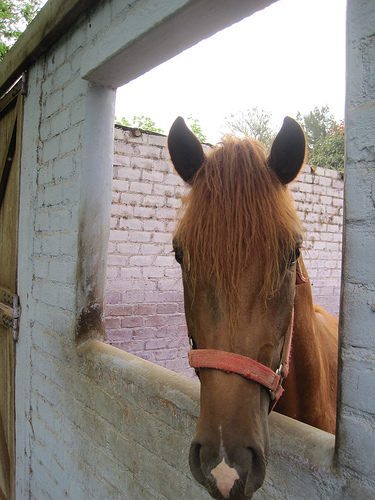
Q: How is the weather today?
A: It is sunny.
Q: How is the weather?
A: It is sunny.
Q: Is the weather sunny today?
A: Yes, it is sunny.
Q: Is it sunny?
A: Yes, it is sunny.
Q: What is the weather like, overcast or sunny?
A: It is sunny.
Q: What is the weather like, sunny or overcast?
A: It is sunny.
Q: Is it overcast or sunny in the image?
A: It is sunny.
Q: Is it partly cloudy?
A: No, it is sunny.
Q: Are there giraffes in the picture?
A: No, there are no giraffes.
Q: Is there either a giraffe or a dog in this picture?
A: No, there are no giraffes or dogs.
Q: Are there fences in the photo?
A: No, there are no fences.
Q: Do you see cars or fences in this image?
A: No, there are no fences or cars.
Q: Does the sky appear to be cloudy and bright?
A: No, the sky is bright but sunny.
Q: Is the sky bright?
A: Yes, the sky is bright.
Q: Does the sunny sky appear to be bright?
A: Yes, the sky is bright.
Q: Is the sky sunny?
A: Yes, the sky is sunny.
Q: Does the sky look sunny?
A: Yes, the sky is sunny.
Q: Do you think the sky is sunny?
A: Yes, the sky is sunny.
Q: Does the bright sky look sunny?
A: Yes, the sky is sunny.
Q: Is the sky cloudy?
A: No, the sky is sunny.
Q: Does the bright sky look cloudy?
A: No, the sky is sunny.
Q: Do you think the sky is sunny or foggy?
A: The sky is sunny.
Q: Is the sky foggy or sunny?
A: The sky is sunny.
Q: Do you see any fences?
A: No, there are no fences.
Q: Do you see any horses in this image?
A: Yes, there is a horse.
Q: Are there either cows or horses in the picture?
A: Yes, there is a horse.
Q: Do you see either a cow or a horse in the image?
A: Yes, there is a horse.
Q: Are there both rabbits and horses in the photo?
A: No, there is a horse but no rabbits.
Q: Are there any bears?
A: No, there are no bears.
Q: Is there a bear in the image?
A: No, there are no bears.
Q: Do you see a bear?
A: No, there are no bears.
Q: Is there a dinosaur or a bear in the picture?
A: No, there are no bears or dinosaurs.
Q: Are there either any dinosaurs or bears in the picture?
A: No, there are no bears or dinosaurs.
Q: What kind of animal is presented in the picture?
A: The animal is a horse.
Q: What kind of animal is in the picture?
A: The animal is a horse.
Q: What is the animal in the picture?
A: The animal is a horse.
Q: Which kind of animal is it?
A: The animal is a horse.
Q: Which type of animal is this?
A: This is a horse.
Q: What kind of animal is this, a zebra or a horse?
A: This is a horse.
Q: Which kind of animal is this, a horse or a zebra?
A: This is a horse.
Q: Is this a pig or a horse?
A: This is a horse.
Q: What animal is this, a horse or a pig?
A: This is a horse.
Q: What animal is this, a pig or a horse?
A: This is a horse.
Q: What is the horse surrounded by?
A: The horse is surrounded by the wall.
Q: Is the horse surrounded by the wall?
A: Yes, the horse is surrounded by the wall.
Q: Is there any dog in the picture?
A: No, there are no dogs.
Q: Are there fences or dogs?
A: No, there are no dogs or fences.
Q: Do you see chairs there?
A: No, there are no chairs.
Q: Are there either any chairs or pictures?
A: No, there are no chairs or pictures.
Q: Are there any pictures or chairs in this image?
A: No, there are no chairs or pictures.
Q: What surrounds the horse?
A: The wall surrounds the horse.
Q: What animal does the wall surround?
A: The wall surrounds the horse.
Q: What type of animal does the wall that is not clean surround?
A: The wall surrounds the horse.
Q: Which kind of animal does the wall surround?
A: The wall surrounds the horse.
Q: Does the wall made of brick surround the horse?
A: Yes, the wall surrounds the horse.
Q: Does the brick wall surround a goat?
A: No, the wall surrounds the horse.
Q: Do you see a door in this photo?
A: Yes, there is a door.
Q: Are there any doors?
A: Yes, there is a door.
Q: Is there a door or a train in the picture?
A: Yes, there is a door.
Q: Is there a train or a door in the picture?
A: Yes, there is a door.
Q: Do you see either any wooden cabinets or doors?
A: Yes, there is a wood door.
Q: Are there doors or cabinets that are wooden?
A: Yes, the door is wooden.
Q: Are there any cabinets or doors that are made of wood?
A: Yes, the door is made of wood.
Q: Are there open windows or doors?
A: Yes, there is an open door.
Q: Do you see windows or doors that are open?
A: Yes, the door is open.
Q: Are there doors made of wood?
A: Yes, there is a door that is made of wood.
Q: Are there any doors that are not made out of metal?
A: Yes, there is a door that is made of wood.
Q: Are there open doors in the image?
A: Yes, there is an open door.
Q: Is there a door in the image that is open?
A: Yes, there is a door that is open.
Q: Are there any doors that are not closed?
A: Yes, there is a open door.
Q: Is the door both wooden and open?
A: Yes, the door is wooden and open.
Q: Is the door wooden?
A: Yes, the door is wooden.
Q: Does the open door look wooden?
A: Yes, the door is wooden.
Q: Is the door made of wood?
A: Yes, the door is made of wood.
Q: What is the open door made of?
A: The door is made of wood.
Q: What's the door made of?
A: The door is made of wood.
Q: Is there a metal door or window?
A: No, there is a door but it is wooden.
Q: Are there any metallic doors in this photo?
A: No, there is a door but it is wooden.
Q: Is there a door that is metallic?
A: No, there is a door but it is wooden.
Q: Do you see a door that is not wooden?
A: No, there is a door but it is wooden.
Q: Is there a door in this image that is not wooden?
A: No, there is a door but it is wooden.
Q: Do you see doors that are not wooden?
A: No, there is a door but it is wooden.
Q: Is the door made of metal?
A: No, the door is made of wood.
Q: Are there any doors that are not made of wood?
A: No, there is a door but it is made of wood.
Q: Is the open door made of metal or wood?
A: The door is made of wood.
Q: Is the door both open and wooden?
A: Yes, the door is open and wooden.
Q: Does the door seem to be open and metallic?
A: No, the door is open but wooden.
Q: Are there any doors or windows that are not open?
A: No, there is a door but it is open.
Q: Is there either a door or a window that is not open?
A: No, there is a door but it is open.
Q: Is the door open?
A: Yes, the door is open.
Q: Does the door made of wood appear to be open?
A: Yes, the door is open.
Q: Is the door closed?
A: No, the door is open.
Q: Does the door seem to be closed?
A: No, the door is open.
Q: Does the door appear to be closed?
A: No, the door is open.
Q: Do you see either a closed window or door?
A: No, there is a door but it is open.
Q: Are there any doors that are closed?
A: No, there is a door but it is open.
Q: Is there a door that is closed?
A: No, there is a door but it is open.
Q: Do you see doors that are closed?
A: No, there is a door but it is open.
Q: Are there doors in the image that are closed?
A: No, there is a door but it is open.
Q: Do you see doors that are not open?
A: No, there is a door but it is open.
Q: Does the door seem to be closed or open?
A: The door is open.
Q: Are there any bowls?
A: No, there are no bowls.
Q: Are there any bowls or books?
A: No, there are no bowls or books.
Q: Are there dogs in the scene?
A: No, there are no dogs.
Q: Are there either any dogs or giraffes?
A: No, there are no dogs or giraffes.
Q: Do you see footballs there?
A: No, there are no footballs.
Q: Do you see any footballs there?
A: No, there are no footballs.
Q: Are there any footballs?
A: No, there are no footballs.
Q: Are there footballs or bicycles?
A: No, there are no footballs or bicycles.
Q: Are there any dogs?
A: No, there are no dogs.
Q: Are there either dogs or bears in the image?
A: No, there are no dogs or bears.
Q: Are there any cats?
A: No, there are no cats.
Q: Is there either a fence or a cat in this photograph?
A: No, there are no cats or fences.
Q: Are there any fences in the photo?
A: No, there are no fences.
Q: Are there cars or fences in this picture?
A: No, there are no fences or cars.